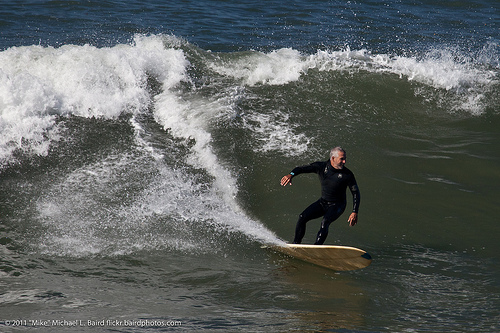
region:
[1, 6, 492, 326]
Man enjoying surfing in Ocean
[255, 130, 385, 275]
Man wearing wet suit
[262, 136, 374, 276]
Man in wet suit surfing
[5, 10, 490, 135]
Waves are high in Ocean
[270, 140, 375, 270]
Man wearing black wet suit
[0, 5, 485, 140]
Water is calm beyond the wave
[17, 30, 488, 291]
Experienced Surfer Conquers Waves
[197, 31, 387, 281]
Man knows how to Surf Well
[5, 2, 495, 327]
Man Surfs in Ocean by Himself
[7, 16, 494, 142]
Tide is coming in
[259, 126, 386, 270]
man is surfing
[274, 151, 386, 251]
man is wearing a one piece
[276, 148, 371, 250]
the man's suit is black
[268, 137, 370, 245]
the suit is wet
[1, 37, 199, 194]
large wave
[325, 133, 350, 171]
man has grey hair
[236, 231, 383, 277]
surfboard is tan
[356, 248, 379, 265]
dark colored tip on the board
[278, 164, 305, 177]
light blue bracelet on his wrist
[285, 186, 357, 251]
his knees are bent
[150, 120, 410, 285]
man in black wetsuit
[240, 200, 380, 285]
front of surfboard out of the water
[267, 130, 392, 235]
arms away from body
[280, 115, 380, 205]
surfer looking over to his left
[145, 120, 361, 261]
surfboard creating trail of white water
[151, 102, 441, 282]
muddy greenish-grey water surrounding surfer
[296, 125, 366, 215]
surfer smiling while turning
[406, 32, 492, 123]
water splashing above and below wave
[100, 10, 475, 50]
bluer water in back of wave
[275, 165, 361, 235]
hands hanging down at end of arms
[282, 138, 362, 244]
this is a man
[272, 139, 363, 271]
the man is sea surfing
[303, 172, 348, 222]
the man is wearing costumes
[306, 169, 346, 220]
the costumes are black in color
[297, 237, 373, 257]
this is a surf board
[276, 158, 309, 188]
the hand is on air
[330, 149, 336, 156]
the hair is grey in color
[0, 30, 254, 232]
waves are behind the man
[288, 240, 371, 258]
the surf board is white in color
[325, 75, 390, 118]
the water is green in color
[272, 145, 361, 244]
man is standing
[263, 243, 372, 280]
surfboard under man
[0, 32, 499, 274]
wave behind man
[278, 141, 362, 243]
man riding the wave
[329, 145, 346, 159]
hair is gray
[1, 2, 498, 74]
water behind wave is blue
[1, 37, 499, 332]
water in front of wave is gray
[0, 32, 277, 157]
top of wave is white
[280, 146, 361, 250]
wetsuit is black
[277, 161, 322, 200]
man's arm is outstretched